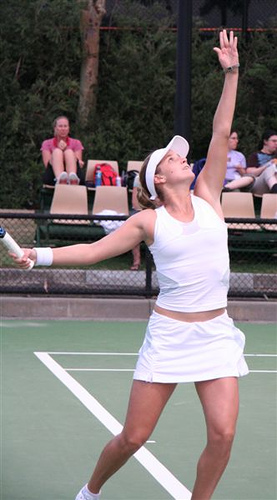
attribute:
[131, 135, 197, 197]
visor — white, sun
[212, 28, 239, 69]
hand — player's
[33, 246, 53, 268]
wrist band — white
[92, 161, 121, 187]
backpack — red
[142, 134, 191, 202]
visor — white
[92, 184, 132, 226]
seat — brown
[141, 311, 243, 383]
skirt — short, white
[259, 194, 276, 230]
seat — in the stands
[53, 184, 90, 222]
seat — brown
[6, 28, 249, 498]
tennis player — female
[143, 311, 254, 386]
skirt — short, white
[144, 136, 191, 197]
visor — white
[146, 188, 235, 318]
tennis top — white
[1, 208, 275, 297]
fence — black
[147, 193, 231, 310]
tank top — white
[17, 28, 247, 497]
player — female, tennis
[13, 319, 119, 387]
court surface — green